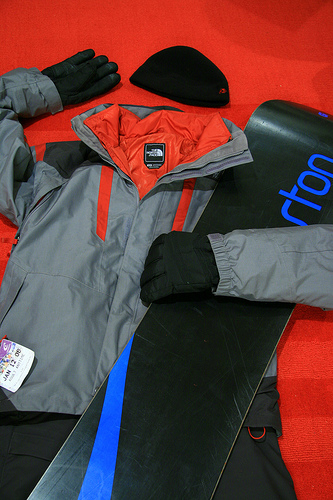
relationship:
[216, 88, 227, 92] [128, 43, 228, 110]
orange logo on black cap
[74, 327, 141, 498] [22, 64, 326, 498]
strip on snowboard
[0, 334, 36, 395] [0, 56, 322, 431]
ticket attached to jacket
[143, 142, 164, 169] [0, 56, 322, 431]
tag in jacket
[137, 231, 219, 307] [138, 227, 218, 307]
glove on hand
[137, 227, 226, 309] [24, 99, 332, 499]
hand holding black snowboard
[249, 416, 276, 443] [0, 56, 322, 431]
tag on jacket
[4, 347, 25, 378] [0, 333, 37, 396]
writing on white tag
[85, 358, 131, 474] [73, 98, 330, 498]
design on snowboard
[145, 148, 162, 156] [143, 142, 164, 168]
white logo on black label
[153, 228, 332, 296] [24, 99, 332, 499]
coat sleeve wrapped around black snowboard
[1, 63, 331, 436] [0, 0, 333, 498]
coat laying on background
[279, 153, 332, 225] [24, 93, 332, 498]
blue lettering on black snowboard